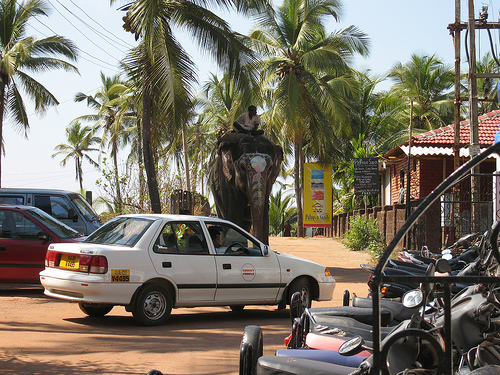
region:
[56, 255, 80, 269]
a yellow license plate with black text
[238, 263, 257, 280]
a round red symbol on a white car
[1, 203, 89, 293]
the side of a red car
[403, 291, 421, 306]
the rearview mirror on a motorcycle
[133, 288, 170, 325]
the back right tire of a white car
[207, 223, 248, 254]
the driver of the white car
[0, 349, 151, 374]
the shadow of a tree on the ground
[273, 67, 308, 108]
Green leaves on a palm tree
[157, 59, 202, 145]
Green leaves on a palm tree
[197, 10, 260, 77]
Green leaves on a palm tree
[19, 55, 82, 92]
Green leaves on a palm tree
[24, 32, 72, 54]
Green leaves on a palm tree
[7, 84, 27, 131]
Green leaves on a palm tree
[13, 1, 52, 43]
Green leaves on a palm tree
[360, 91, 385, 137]
Green leaves on a palm tree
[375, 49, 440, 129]
Green leaves on a palm tree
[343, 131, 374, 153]
Green leaves on a palm tree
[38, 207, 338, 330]
car is white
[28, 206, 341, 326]
car is on street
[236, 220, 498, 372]
Bikes are parked on the right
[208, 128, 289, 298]
Elephant standing on the street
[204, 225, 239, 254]
Person in white car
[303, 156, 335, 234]
yellow sign down the road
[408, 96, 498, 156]
tile roof on the building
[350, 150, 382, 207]
sign down the road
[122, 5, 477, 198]
Tall palm trees under the sly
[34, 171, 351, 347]
this is a car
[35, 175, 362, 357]
the car is white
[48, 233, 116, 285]
yellow car license plate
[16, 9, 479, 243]
palm trees in background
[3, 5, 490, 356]
a bright and clear day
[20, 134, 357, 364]
the car is parked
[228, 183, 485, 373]
a row of parked motor bikes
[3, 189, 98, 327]
this is a red car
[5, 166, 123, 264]
van parked next to car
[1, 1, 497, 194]
light in daytime sky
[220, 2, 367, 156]
leaves of palm trees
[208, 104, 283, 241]
man seated on elephant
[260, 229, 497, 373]
tops of parked motorbikes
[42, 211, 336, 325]
side of white car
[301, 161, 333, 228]
yellow vertical hanging banner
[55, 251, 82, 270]
license plate on car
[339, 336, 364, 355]
sideview mirror of bike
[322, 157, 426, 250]
wall in front of building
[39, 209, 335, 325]
small white car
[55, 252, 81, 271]
yellow and black license plate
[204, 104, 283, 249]
man riding on top of an elephant